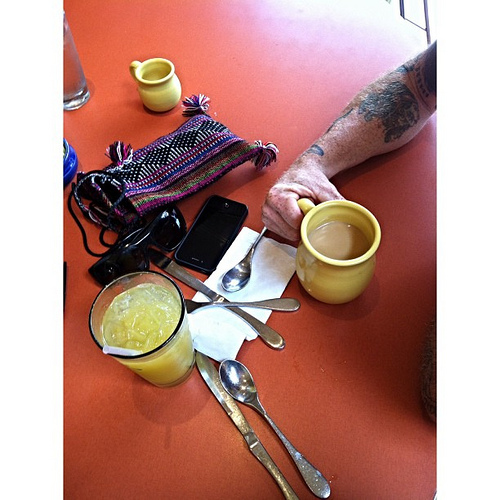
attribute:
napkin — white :
[217, 232, 300, 310]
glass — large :
[81, 261, 203, 392]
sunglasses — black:
[86, 205, 188, 283]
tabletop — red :
[64, 0, 436, 497]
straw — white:
[101, 342, 146, 356]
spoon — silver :
[290, 361, 332, 489]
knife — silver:
[195, 347, 288, 495]